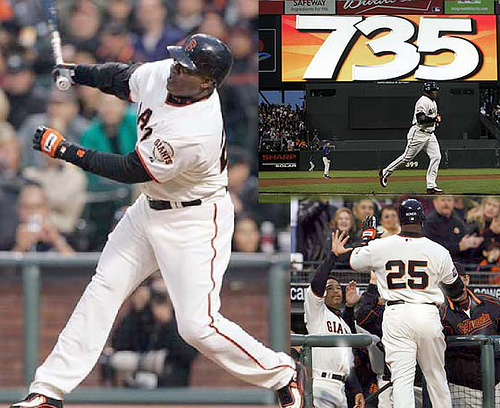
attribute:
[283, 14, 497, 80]
number — 735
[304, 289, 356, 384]
white shirt — on woman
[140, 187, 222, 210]
belt — black, leather, cinched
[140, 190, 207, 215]
leather belt — black, cinched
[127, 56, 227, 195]
shirt — white 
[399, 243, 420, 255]
white — on train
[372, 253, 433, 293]
25 — on train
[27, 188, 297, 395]
pants — white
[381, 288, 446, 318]
belt — black, leather, cinched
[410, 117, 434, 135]
belt — black , leather 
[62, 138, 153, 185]
sleeve — long, black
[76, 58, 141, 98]
sleeve — long, black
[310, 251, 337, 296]
sleeve — long, black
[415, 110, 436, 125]
sleeve — long, black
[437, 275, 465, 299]
sleeve — long, black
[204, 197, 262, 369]
stripe — red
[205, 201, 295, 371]
stripe — red 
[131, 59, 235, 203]
shirt — white 